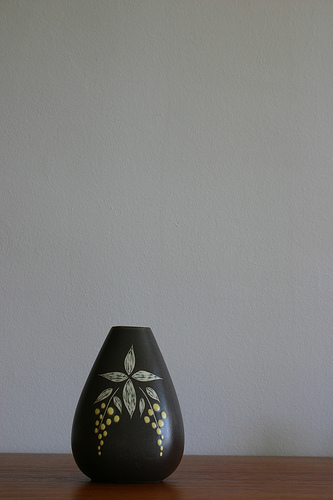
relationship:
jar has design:
[69, 322, 185, 481] [97, 349, 169, 459]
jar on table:
[69, 322, 185, 481] [1, 453, 330, 499]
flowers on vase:
[102, 342, 163, 423] [52, 320, 195, 484]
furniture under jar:
[5, 451, 322, 493] [69, 322, 185, 481]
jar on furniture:
[69, 322, 185, 481] [5, 451, 333, 500]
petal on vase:
[139, 386, 158, 401] [70, 315, 187, 490]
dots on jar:
[142, 406, 162, 433] [69, 322, 185, 481]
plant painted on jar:
[91, 340, 169, 460] [69, 322, 185, 481]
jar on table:
[69, 322, 185, 481] [0, 448, 333, 498]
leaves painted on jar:
[87, 339, 168, 458] [69, 322, 185, 481]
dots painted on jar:
[91, 395, 120, 456] [69, 322, 185, 481]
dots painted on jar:
[143, 399, 169, 456] [69, 322, 185, 481]